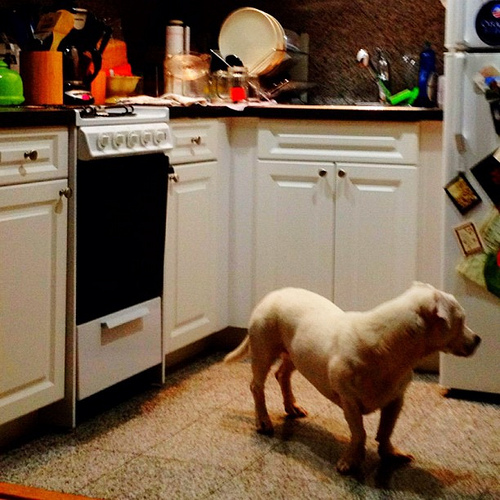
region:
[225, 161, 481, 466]
Dog standing in the kitchen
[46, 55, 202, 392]
Oven in a kitchen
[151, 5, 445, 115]
Dishes next to a sink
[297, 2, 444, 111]
Kitchen sink with dish soap and sponges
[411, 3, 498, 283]
Items on a refrigerator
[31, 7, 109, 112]
Utensils on a kitchen counter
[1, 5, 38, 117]
Green teapot on a kitchen counter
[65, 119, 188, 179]
White buttons on an oven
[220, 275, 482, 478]
Chubby white dog standing in a kitchen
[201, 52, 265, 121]
Glass mug on a kitchen counter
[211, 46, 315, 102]
A silver dish strainer.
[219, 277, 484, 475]
A beige colored dog.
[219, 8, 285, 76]
Round beige plates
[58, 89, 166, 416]
A black and white stove.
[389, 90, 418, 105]
A green dish sponge.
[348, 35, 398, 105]
Silver sink fixtures.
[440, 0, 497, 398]
A white refrigerator.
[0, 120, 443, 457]
White cabinets.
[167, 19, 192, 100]
A roll of paper towels.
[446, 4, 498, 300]
Magnets on the refrigerator.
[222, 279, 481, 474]
light brown dog standing in kitchen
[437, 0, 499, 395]
white refridgerator/freezer unit in the kitchen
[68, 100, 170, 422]
white and black oven/stove in kitchen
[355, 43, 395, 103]
silver chrome water faucet over sink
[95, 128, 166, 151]
round white knobs on front of oven/stove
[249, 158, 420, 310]
white cabinet underneath sink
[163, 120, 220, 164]
white drawer to right of oven/stove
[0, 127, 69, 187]
white drawer to the left of oven/stove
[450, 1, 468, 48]
white handle on the front of the freezer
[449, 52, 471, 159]
white handle on the front of the refrigerator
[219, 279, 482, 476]
white dog standing in the kitchen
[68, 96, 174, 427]
a white oven next to the dog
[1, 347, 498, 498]
tiled floor under the dog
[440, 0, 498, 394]
white refrigerator in the kitchen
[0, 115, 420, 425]
white cabinets in kitchen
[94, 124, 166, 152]
controls on oven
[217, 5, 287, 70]
white plates on metal stand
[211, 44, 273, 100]
metal stand for plates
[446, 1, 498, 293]
decorations on the refrigerator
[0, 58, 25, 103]
green kettle on counter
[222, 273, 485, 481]
a small white dog standing in the kitchen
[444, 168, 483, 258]
rectangular shaped magnets on the refrigerator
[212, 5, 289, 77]
white plates in the drying rack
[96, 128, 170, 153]
five white knobs on the oven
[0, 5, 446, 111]
a bunch of clutter on top of the kitchen counters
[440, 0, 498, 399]
a white refrigerator with magnets on it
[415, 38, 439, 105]
a blue bottle of dish soap near the sink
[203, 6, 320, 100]
a drying rack with plates on it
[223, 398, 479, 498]
the shadow of the dog on the floor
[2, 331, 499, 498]
a tiled kitchen floor with brown and white speckles